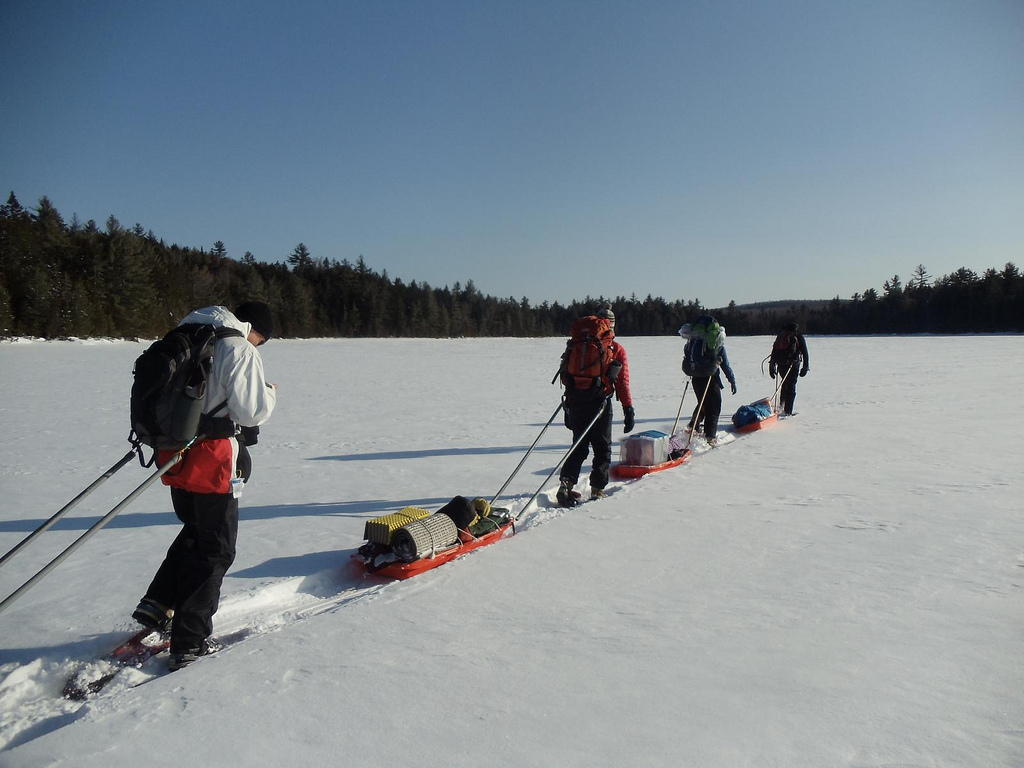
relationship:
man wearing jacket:
[93, 322, 312, 550] [93, 322, 312, 550]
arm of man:
[157, 305, 347, 480] [157, 305, 347, 480]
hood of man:
[169, 284, 318, 418] [169, 284, 318, 418]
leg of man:
[122, 501, 282, 632] [122, 249, 282, 632]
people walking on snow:
[172, 317, 1014, 647] [172, 317, 1014, 647]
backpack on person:
[101, 311, 320, 471] [101, 311, 320, 471]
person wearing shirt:
[101, 311, 320, 471] [101, 311, 320, 471]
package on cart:
[347, 463, 510, 559] [347, 463, 510, 559]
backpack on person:
[584, 317, 698, 419] [584, 317, 698, 419]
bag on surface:
[707, 369, 867, 471] [707, 369, 867, 471]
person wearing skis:
[72, 311, 308, 703] [43, 545, 323, 694]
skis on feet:
[43, 545, 323, 694] [43, 545, 323, 694]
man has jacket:
[93, 323, 312, 551] [119, 320, 385, 548]